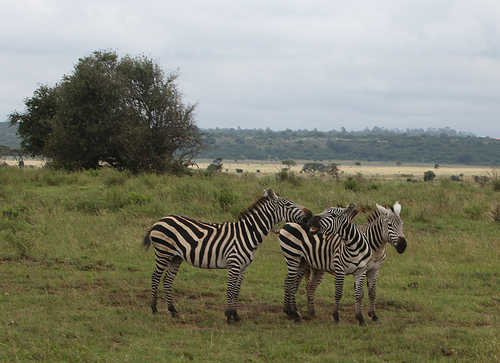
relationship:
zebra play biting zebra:
[276, 203, 370, 323] [142, 189, 312, 323]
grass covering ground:
[28, 300, 162, 361] [0, 162, 499, 362]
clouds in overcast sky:
[5, 2, 498, 139] [1, 0, 500, 142]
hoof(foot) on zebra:
[149, 305, 161, 313] [142, 189, 312, 323]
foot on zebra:
[280, 268, 312, 310] [133, 176, 319, 356]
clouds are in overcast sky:
[0, 0, 499, 138] [1, 0, 498, 142]